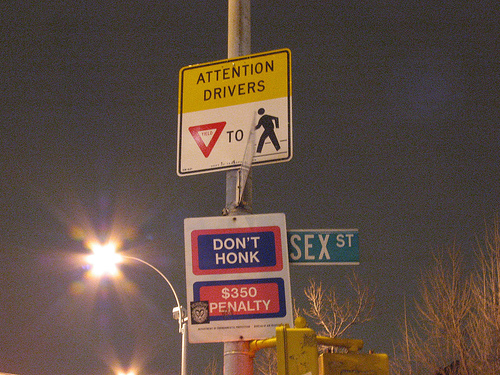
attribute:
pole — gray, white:
[222, 0, 257, 357]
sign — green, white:
[285, 225, 363, 268]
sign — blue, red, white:
[183, 216, 293, 342]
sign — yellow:
[177, 48, 294, 170]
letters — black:
[193, 58, 279, 100]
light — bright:
[65, 219, 139, 288]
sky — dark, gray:
[0, 1, 499, 374]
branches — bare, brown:
[299, 258, 499, 374]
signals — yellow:
[251, 320, 393, 373]